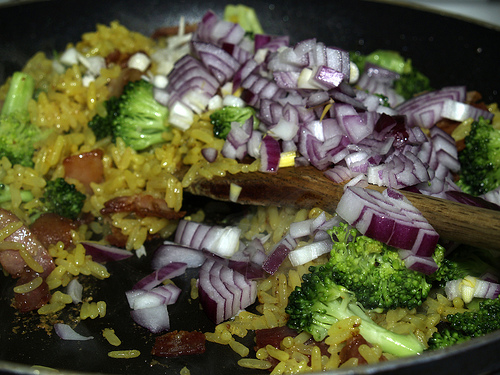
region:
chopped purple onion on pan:
[360, 204, 395, 269]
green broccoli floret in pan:
[277, 305, 416, 330]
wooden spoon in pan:
[257, 165, 306, 217]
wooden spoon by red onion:
[320, 173, 364, 223]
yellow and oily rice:
[88, 135, 165, 215]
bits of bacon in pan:
[65, 140, 105, 206]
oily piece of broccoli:
[105, 76, 175, 152]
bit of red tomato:
[46, 145, 96, 194]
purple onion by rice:
[201, 256, 290, 334]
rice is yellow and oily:
[13, 160, 49, 205]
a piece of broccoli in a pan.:
[84, 73, 174, 157]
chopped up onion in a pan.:
[117, 195, 295, 337]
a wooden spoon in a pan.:
[198, 153, 498, 274]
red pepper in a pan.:
[61, 133, 111, 198]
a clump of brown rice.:
[46, 63, 109, 112]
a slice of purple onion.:
[179, 268, 264, 323]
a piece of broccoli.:
[347, 39, 437, 85]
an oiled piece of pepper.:
[0, 200, 64, 277]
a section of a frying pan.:
[394, 25, 446, 60]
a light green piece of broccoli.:
[80, 74, 184, 173]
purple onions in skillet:
[181, 37, 468, 218]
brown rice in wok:
[21, 47, 214, 209]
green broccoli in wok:
[101, 87, 168, 148]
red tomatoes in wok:
[56, 135, 181, 230]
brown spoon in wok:
[186, 157, 496, 265]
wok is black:
[1, 1, 481, 371]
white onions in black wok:
[111, 33, 247, 146]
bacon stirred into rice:
[154, 300, 331, 373]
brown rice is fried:
[111, 88, 254, 233]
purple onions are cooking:
[141, 26, 478, 250]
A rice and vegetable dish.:
[0, 16, 496, 372]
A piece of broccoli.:
[280, 265, 421, 360]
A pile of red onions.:
[151, 10, 496, 206]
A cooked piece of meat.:
[96, 190, 181, 217]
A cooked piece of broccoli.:
[110, 72, 177, 152]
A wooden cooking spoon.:
[194, 157, 499, 252]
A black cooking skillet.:
[0, 0, 499, 373]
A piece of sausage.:
[1, 208, 56, 279]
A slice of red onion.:
[198, 258, 261, 324]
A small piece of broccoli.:
[41, 175, 87, 222]